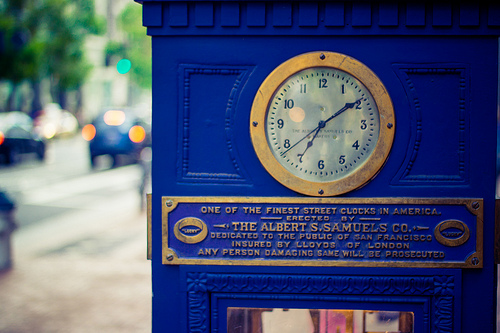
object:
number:
[296, 152, 307, 164]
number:
[314, 75, 331, 90]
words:
[198, 205, 446, 259]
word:
[223, 205, 238, 216]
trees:
[99, 4, 150, 97]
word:
[240, 204, 265, 216]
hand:
[301, 122, 325, 155]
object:
[135, 0, 500, 333]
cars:
[78, 103, 148, 175]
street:
[3, 132, 150, 332]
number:
[273, 114, 287, 135]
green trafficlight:
[113, 57, 133, 75]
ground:
[0, 270, 145, 333]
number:
[351, 138, 360, 151]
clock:
[249, 48, 399, 199]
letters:
[199, 204, 208, 214]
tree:
[3, 0, 62, 120]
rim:
[248, 49, 395, 199]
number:
[339, 79, 348, 97]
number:
[335, 149, 350, 169]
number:
[314, 158, 326, 170]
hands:
[324, 97, 362, 121]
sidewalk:
[0, 112, 102, 152]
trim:
[247, 45, 400, 196]